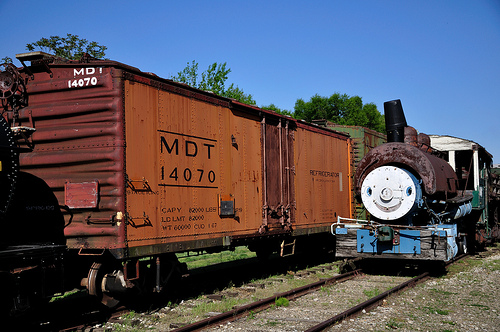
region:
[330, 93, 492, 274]
the train on the tracks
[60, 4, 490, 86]
the sky is blue and clear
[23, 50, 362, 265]
the train car beside the train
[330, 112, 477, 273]
the train is old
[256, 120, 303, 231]
the door on the train car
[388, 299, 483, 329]
gravel beside the tracks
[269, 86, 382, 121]
the trees behind the train car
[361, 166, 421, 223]
smiley face on the train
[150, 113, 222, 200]
writing on the train car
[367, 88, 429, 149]
the smoke stack on the train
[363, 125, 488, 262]
the head of a train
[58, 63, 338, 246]
the compartment of a train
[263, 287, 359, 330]
the rails of a railway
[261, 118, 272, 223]
a metal bar on the train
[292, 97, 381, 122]
green leaves of a tree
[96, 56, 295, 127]
the top of a train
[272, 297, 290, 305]
green grass on the rail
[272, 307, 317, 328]
pebbles between the two rails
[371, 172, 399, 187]
white paint on the front of the train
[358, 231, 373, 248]
blue paint on the train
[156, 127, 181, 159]
The letter is black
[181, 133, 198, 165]
The letter is black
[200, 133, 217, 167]
The letter is black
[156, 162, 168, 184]
The number is black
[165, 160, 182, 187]
The number is black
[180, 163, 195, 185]
The number is black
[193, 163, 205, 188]
The number is black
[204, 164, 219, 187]
The number is black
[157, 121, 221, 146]
The line is black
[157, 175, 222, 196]
The line is black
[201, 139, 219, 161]
The letter is brown.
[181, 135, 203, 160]
The letter is brown.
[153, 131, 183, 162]
The letter is brown.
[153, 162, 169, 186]
The number is brown.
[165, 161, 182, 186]
The number is brown.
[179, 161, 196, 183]
The number is brown.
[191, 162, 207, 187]
The number is brown.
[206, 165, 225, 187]
The number is brown.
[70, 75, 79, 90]
The number is white.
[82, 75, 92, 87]
The number is white.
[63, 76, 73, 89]
The number is white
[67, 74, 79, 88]
The number is white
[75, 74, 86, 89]
The number is white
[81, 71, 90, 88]
The number is white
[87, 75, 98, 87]
The number is white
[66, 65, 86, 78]
The letter is white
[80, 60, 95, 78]
The letter is white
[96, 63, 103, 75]
The letter is white